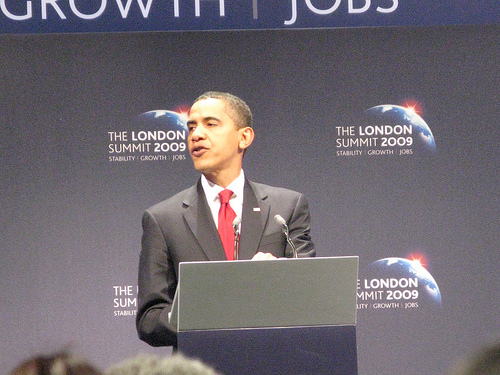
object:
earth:
[353, 99, 438, 161]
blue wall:
[49, 160, 116, 253]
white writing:
[335, 124, 412, 148]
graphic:
[328, 97, 437, 159]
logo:
[333, 124, 415, 158]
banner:
[1, 0, 499, 35]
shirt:
[200, 170, 245, 260]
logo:
[106, 128, 189, 162]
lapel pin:
[252, 207, 260, 211]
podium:
[167, 254, 372, 370]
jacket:
[134, 169, 316, 349]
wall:
[47, 65, 442, 370]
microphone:
[273, 215, 299, 259]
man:
[133, 90, 317, 359]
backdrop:
[0, 0, 500, 375]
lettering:
[2, 0, 404, 27]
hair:
[190, 90, 255, 127]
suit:
[137, 168, 317, 347]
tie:
[217, 189, 236, 261]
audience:
[0, 340, 499, 373]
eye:
[207, 122, 218, 127]